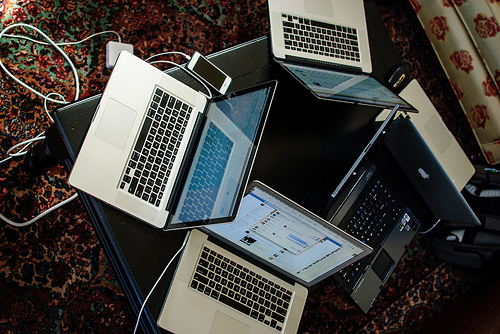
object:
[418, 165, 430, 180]
logo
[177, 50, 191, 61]
plug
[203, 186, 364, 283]
facebook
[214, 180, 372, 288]
screen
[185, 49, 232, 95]
phone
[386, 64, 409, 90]
computer mouse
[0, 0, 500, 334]
table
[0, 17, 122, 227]
cords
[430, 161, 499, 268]
black backpack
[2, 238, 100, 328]
ground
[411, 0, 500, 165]
couch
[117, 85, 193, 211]
keys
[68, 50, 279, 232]
laptop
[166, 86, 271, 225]
screen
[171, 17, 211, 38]
floor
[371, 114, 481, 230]
screen